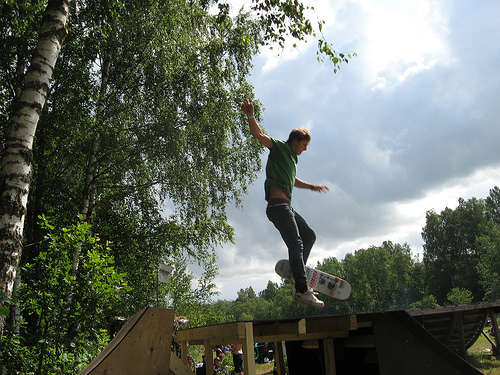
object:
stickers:
[313, 270, 327, 287]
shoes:
[289, 288, 328, 306]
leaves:
[104, 137, 114, 148]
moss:
[3, 110, 33, 158]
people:
[191, 343, 280, 374]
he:
[235, 97, 383, 346]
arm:
[224, 84, 275, 149]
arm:
[284, 168, 332, 203]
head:
[269, 105, 317, 162]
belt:
[264, 184, 301, 217]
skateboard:
[266, 249, 366, 299]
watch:
[240, 105, 268, 124]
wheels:
[320, 280, 343, 297]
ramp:
[81, 287, 500, 375]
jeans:
[255, 202, 338, 295]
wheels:
[282, 264, 296, 277]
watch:
[244, 111, 257, 123]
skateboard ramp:
[95, 301, 178, 372]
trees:
[0, 0, 108, 340]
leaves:
[447, 291, 459, 299]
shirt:
[260, 126, 301, 197]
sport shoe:
[290, 282, 325, 310]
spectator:
[190, 345, 215, 367]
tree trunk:
[0, 58, 48, 341]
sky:
[161, 0, 494, 298]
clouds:
[196, 0, 499, 288]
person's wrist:
[241, 110, 260, 125]